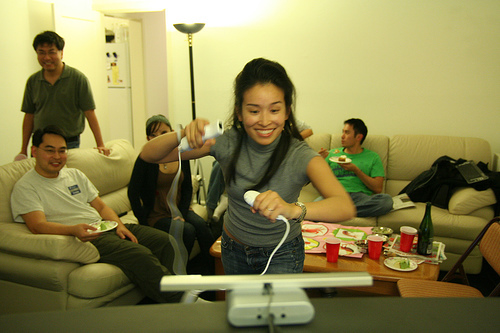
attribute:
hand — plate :
[68, 222, 101, 245]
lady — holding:
[147, 70, 352, 287]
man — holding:
[33, 133, 153, 302]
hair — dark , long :
[234, 58, 294, 89]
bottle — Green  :
[415, 195, 431, 255]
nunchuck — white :
[248, 190, 258, 197]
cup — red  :
[324, 239, 338, 260]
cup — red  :
[364, 237, 385, 258]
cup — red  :
[395, 230, 416, 250]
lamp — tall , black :
[175, 20, 209, 118]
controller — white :
[244, 190, 254, 206]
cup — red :
[324, 244, 340, 262]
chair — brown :
[397, 222, 495, 294]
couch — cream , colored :
[88, 151, 115, 181]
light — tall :
[173, 22, 202, 116]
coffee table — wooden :
[357, 257, 371, 267]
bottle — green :
[419, 200, 437, 250]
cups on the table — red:
[321, 218, 424, 265]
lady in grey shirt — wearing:
[201, 128, 309, 254]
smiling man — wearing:
[35, 139, 82, 177]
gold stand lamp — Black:
[172, 15, 216, 135]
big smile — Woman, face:
[237, 103, 297, 146]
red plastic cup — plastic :
[393, 220, 420, 254]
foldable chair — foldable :
[393, 225, 499, 308]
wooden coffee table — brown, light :
[301, 218, 455, 297]